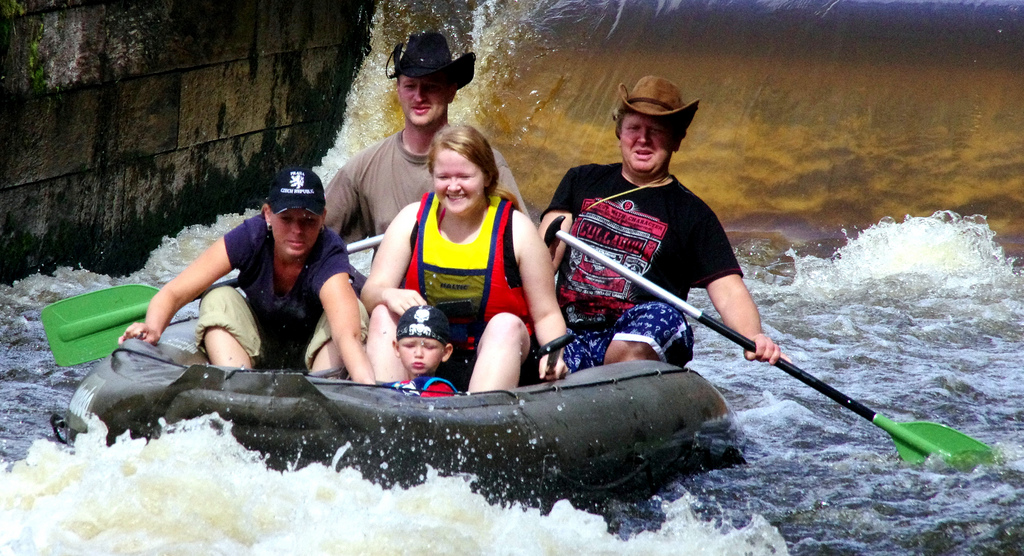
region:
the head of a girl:
[411, 122, 509, 222]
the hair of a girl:
[422, 128, 479, 152]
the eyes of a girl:
[441, 162, 470, 185]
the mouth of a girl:
[441, 192, 481, 203]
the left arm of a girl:
[482, 221, 575, 343]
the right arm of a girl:
[371, 203, 414, 322]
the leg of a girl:
[456, 320, 546, 396]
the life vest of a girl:
[415, 218, 549, 320]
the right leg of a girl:
[356, 303, 417, 373]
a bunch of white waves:
[198, 432, 511, 554]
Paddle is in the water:
[552, 224, 993, 531]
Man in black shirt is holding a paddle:
[542, 60, 986, 538]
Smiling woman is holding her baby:
[370, 121, 560, 422]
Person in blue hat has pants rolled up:
[136, 151, 399, 434]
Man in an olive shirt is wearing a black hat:
[279, 16, 621, 402]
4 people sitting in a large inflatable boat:
[78, 31, 996, 521]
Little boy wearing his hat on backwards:
[380, 287, 478, 409]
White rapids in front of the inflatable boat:
[10, 364, 693, 552]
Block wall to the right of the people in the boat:
[17, 19, 489, 308]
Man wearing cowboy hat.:
[378, 26, 471, 203]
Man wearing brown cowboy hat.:
[610, 72, 699, 364]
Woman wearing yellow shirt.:
[416, 127, 511, 419]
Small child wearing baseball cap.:
[388, 292, 456, 403]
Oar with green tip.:
[552, 220, 989, 484]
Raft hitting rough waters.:
[3, 331, 573, 553]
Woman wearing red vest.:
[381, 127, 541, 394]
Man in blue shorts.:
[534, 87, 697, 383]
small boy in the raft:
[387, 302, 461, 394]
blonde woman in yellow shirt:
[362, 127, 568, 394]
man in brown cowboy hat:
[538, 80, 779, 378]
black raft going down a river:
[71, 327, 739, 505]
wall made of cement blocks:
[4, 5, 377, 282]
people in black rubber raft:
[64, 25, 742, 507]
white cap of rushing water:
[6, 411, 787, 554]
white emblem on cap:
[271, 163, 326, 222]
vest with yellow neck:
[404, 194, 526, 318]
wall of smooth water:
[332, 0, 1022, 273]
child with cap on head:
[391, 301, 458, 394]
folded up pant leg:
[196, 278, 261, 364]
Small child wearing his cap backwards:
[387, 294, 461, 398]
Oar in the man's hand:
[552, 224, 1009, 484]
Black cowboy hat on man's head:
[382, 23, 472, 92]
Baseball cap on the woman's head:
[265, 157, 328, 227]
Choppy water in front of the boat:
[0, 414, 774, 554]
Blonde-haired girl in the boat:
[359, 121, 562, 318]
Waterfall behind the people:
[356, 0, 1020, 286]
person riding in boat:
[388, 296, 458, 401]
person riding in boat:
[117, 160, 380, 394]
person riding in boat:
[357, 121, 564, 390]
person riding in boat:
[539, 73, 793, 380]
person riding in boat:
[332, 29, 535, 254]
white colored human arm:
[138, 239, 234, 339]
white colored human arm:
[506, 209, 571, 358]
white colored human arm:
[364, 200, 419, 308]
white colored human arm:
[707, 272, 755, 339]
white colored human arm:
[540, 209, 566, 270]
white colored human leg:
[198, 318, 243, 370]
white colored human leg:
[310, 339, 339, 375]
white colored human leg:
[370, 293, 405, 389]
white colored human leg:
[464, 315, 526, 393]